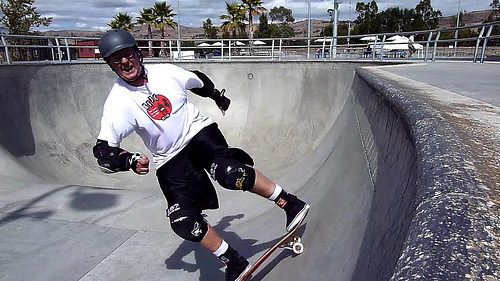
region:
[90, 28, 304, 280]
Man riding skateboard on ramp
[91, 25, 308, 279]
Man wearing black helmet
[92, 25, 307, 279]
Man wearing white shirt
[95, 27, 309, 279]
Man wearing black shorts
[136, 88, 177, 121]
Red logo on shirt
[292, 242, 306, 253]
White wheel on skateboard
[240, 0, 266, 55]
Palm tree near white umbrella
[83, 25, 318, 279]
Man wearing knee gear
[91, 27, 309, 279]
Man wearing elbow pads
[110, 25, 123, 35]
Small hole on black helmet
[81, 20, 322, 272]
skateboarder inside curved depression in park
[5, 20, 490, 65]
metal railing along top of park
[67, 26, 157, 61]
low brown building behind head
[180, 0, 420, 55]
umbrellas and seating near palm trees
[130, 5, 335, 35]
mountains and clouds in the distance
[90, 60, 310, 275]
skateboarder wearing black and white outfit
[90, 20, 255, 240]
black helmet and padding at elbows and knees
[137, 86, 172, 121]
red circle with black and white markings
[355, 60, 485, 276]
gray and white rim on skateboarding venue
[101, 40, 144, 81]
skateboarder with happy expression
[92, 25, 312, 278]
senior citizen on skateboard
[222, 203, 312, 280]
skateboard with white wheel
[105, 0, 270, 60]
palm street in the background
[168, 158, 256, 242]
big, black knee-pads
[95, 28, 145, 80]
black helmet on head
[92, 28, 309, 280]
man wearing black shorts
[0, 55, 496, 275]
concrete skating rink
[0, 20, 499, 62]
metal fence around skating rink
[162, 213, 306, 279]
man's shadow on the ground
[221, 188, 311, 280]
pair of black sneakers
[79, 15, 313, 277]
guy wearing black helmet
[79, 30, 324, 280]
guy wearing white and red shirt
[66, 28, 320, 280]
guy wearing black shorts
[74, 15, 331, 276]
guy wearing glasses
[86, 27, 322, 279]
guy wearing black tennis shoes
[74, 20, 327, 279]
guy wearing arm pads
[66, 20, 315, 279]
guy wearing knee pads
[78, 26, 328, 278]
guy wearing black and white tennis shoes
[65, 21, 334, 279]
guy on skateboard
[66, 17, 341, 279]
guy wearing safety attire on skateboard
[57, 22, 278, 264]
Man riding on a skateboard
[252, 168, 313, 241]
Black and white sneakers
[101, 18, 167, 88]
Man is wearing a helmet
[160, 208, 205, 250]
Knee pad on the leg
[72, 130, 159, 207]
Elbow pad on man's arm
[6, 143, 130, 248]
Shadow on the concrete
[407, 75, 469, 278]
Pebbles on the side of ramp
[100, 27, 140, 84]
The man is happy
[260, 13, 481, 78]
Steel railing around the skate park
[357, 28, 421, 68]
White tent in the background